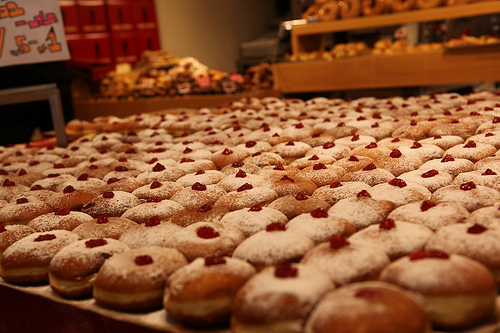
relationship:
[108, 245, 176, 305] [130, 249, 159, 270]
cream puff with fruit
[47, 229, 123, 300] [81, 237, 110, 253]
cream puff with fruit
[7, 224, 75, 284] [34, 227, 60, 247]
cream puff with fruit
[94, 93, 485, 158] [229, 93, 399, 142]
cream puffs with fruit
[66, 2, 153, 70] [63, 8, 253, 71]
box with wall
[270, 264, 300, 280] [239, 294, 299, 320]
jelly filled doughnut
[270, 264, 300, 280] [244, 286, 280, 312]
jelly filled doughnut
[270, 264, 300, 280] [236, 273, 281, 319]
jelly filled doughnut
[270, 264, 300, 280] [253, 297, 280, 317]
jelly filled doughnut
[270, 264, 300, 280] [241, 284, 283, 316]
jelly filled doughnut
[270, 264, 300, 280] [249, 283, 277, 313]
jelly filled doughnut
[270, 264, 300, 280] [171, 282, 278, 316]
jelly filled doughnuts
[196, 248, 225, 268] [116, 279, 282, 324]
jelly filled doughnuts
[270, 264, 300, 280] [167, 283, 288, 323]
jelly filled doughnut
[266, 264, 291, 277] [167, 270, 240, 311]
jelly on pastry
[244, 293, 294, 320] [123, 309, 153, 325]
pastry on table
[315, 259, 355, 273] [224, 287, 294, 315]
sugar on top pastry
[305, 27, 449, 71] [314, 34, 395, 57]
stand for other pastries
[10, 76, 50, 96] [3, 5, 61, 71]
table holding up sign